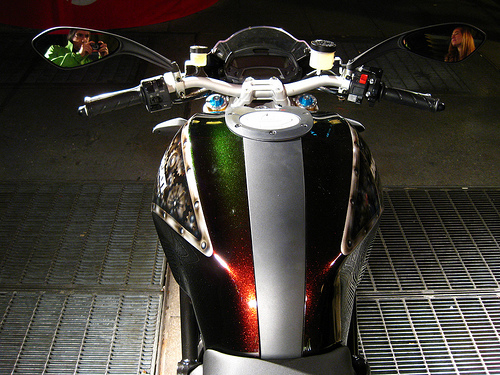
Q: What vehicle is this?
A: Motorcycle.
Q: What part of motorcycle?
A: Handlebar.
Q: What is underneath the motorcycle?
A: Metal grates.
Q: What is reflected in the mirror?
A: A man.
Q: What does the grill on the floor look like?
A: Lots of holes.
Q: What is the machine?
A: Motorcycle.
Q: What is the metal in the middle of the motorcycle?
A: A stripe.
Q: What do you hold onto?
A: Handlebars.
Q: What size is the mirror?
A: Small.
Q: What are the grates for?
A: Drainage.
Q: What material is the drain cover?
A: Metal.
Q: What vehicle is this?
A: Motorcycle.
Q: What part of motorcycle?
A: Handlebars.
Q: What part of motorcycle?
A: Front.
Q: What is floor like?
A: Grated.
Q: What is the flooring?
A: Grating.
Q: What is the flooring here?
A: Grating.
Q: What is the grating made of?
A: Metal.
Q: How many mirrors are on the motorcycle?
A: Two.